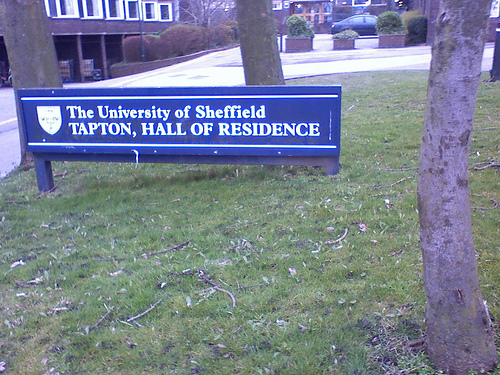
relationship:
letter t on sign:
[62, 96, 77, 123] [11, 74, 364, 195]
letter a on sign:
[76, 122, 87, 142] [7, 70, 355, 166]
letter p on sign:
[84, 114, 104, 138] [6, 65, 352, 197]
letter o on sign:
[105, 122, 121, 138] [12, 85, 343, 158]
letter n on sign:
[116, 118, 135, 135] [6, 64, 386, 196]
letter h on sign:
[136, 118, 155, 138] [11, 74, 364, 195]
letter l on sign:
[163, 117, 177, 137] [6, 65, 352, 197]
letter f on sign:
[201, 118, 217, 139] [9, 72, 360, 173]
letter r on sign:
[216, 118, 232, 133] [3, 69, 392, 209]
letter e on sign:
[225, 114, 241, 138] [11, 74, 364, 195]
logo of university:
[34, 105, 64, 136] [1, 1, 499, 372]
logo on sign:
[34, 105, 64, 136] [8, 68, 358, 208]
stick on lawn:
[187, 267, 246, 319] [1, 63, 499, 373]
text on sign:
[62, 104, 322, 138] [12, 84, 343, 161]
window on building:
[44, 0, 55, 20] [1, 0, 183, 91]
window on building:
[59, 0, 64, 18] [1, 0, 183, 91]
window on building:
[44, 0, 61, 18] [1, 0, 183, 91]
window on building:
[158, 0, 174, 23] [1, 0, 183, 91]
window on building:
[122, 3, 140, 19] [1, 0, 183, 91]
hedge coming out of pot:
[373, 9, 406, 35] [284, 28, 316, 55]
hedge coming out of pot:
[376, 0, 411, 34] [376, 30, 412, 49]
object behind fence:
[53, 57, 77, 82] [55, 62, 109, 79]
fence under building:
[55, 62, 109, 79] [1, 0, 183, 91]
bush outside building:
[282, 13, 317, 39] [1, 0, 183, 91]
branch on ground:
[123, 297, 165, 324] [1, 33, 491, 370]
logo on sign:
[34, 100, 64, 135] [12, 84, 343, 161]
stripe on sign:
[23, 139, 339, 150] [12, 84, 343, 161]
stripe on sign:
[17, 92, 333, 100] [12, 84, 343, 161]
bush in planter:
[282, 13, 317, 39] [284, 32, 311, 53]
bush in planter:
[373, 9, 403, 32] [376, 27, 409, 51]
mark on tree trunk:
[454, 171, 468, 191] [415, 0, 496, 373]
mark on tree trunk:
[450, 286, 467, 305] [415, 0, 496, 373]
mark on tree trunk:
[436, 166, 446, 176] [415, 0, 496, 373]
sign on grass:
[12, 84, 343, 161] [1, 65, 497, 368]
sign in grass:
[12, 85, 343, 158] [111, 180, 344, 338]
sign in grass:
[12, 85, 343, 158] [122, 216, 321, 354]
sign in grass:
[12, 85, 343, 158] [99, 203, 309, 363]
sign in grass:
[12, 85, 343, 158] [40, 199, 275, 354]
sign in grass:
[12, 85, 343, 158] [90, 200, 289, 356]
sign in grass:
[12, 85, 343, 158] [157, 220, 330, 349]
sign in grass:
[12, 84, 343, 161] [23, 145, 417, 347]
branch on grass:
[123, 297, 165, 324] [33, 182, 383, 343]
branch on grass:
[123, 297, 165, 324] [23, 166, 439, 339]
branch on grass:
[123, 297, 165, 324] [28, 153, 428, 363]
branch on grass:
[123, 297, 165, 324] [48, 173, 363, 344]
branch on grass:
[388, 168, 411, 198] [28, 174, 433, 369]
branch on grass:
[472, 151, 498, 184] [40, 164, 499, 342]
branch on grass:
[123, 297, 165, 324] [33, 167, 457, 372]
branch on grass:
[88, 301, 123, 331] [21, 181, 431, 350]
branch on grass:
[35, 199, 76, 233] [26, 149, 481, 356]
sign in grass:
[12, 85, 343, 158] [21, 159, 364, 326]